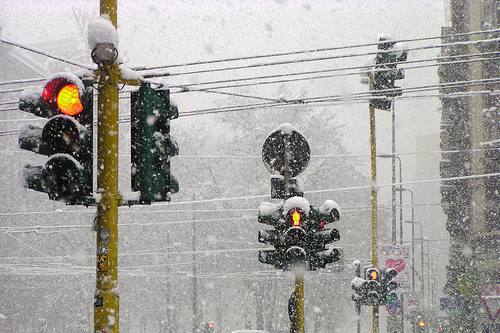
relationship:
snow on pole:
[85, 12, 120, 47] [91, 1, 121, 331]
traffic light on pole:
[18, 64, 181, 205] [92, 1, 115, 331]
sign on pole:
[246, 108, 328, 196] [289, 268, 311, 331]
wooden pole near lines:
[188, 191, 203, 331] [7, 27, 499, 279]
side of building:
[5, 39, 100, 316] [0, 36, 150, 329]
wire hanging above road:
[152, 17, 494, 136] [344, 310, 409, 333]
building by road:
[428, 5, 498, 313] [330, 299, 440, 330]